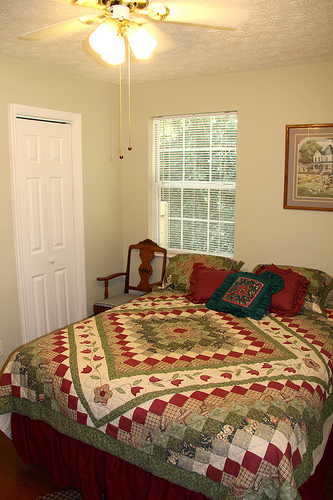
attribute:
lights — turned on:
[89, 9, 170, 70]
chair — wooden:
[95, 237, 165, 310]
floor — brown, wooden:
[0, 428, 81, 498]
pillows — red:
[186, 260, 313, 337]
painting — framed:
[273, 112, 331, 216]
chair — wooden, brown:
[112, 226, 171, 288]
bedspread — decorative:
[0, 253, 331, 499]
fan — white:
[16, 0, 253, 55]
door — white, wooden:
[13, 113, 80, 339]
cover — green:
[212, 272, 278, 315]